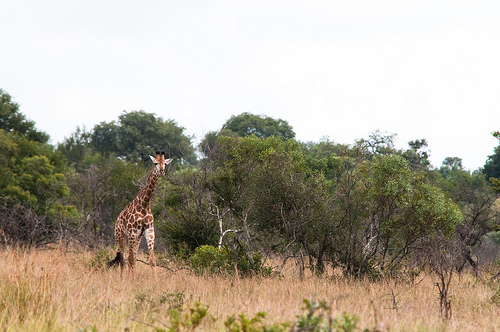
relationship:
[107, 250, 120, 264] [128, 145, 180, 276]
tail of giraffe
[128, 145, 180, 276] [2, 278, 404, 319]
giraffe in savannah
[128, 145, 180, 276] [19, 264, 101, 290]
giraffe on ground